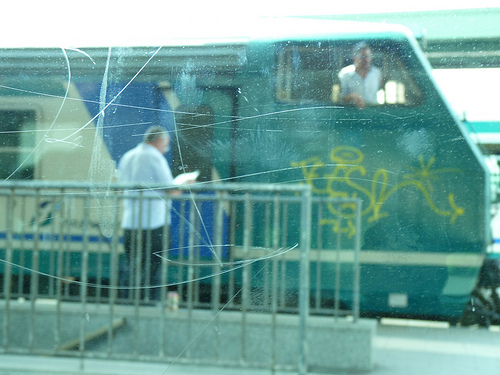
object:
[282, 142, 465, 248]
graffitti on train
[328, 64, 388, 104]
white shirt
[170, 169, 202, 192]
newspaper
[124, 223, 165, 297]
black pants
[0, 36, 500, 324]
train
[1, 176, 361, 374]
metal fences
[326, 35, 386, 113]
train driver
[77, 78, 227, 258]
blue  siding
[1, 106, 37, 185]
train window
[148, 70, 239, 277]
train door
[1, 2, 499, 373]
photo  not clear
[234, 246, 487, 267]
white strip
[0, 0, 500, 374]
outside scene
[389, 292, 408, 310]
white square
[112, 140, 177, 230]
shirt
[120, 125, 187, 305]
man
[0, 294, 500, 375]
path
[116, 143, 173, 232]
clothes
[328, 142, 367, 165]
circle